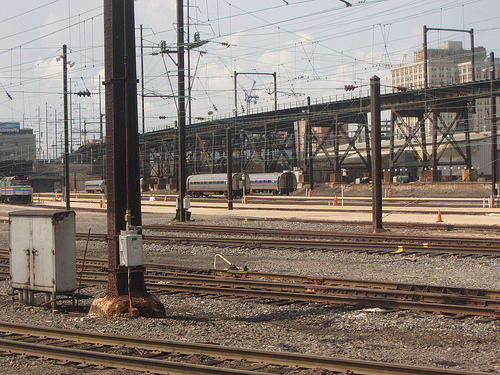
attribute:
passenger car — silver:
[187, 170, 289, 197]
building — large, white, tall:
[391, 41, 500, 170]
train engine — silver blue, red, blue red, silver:
[3, 170, 35, 208]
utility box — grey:
[7, 204, 78, 304]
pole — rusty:
[120, 2, 132, 215]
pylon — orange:
[435, 212, 447, 224]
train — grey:
[86, 177, 110, 197]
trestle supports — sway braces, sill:
[304, 111, 473, 188]